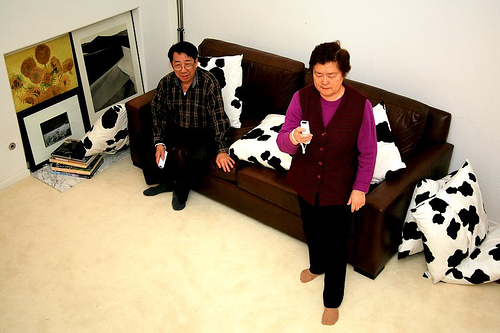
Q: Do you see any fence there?
A: No, there are no fences.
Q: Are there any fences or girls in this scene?
A: No, there are no fences or girls.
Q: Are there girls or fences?
A: No, there are no fences or girls.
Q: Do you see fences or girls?
A: No, there are no fences or girls.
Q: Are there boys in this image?
A: No, there are no boys.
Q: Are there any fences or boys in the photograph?
A: No, there are no boys or fences.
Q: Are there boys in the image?
A: No, there are no boys.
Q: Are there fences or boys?
A: No, there are no boys or fences.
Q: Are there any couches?
A: Yes, there is a couch.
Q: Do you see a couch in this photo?
A: Yes, there is a couch.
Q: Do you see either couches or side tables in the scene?
A: Yes, there is a couch.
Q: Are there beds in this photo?
A: No, there are no beds.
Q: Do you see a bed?
A: No, there are no beds.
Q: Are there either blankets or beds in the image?
A: No, there are no beds or blankets.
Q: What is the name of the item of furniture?
A: The piece of furniture is a couch.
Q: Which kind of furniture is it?
A: The piece of furniture is a couch.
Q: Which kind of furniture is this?
A: This is a couch.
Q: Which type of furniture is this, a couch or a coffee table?
A: This is a couch.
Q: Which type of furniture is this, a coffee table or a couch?
A: This is a couch.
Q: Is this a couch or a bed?
A: This is a couch.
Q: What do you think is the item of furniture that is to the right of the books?
A: The piece of furniture is a couch.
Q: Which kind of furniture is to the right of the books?
A: The piece of furniture is a couch.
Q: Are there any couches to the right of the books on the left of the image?
A: Yes, there is a couch to the right of the books.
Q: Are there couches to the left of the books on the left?
A: No, the couch is to the right of the books.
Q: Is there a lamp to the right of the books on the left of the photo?
A: No, there is a couch to the right of the books.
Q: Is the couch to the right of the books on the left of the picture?
A: Yes, the couch is to the right of the books.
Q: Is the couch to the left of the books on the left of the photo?
A: No, the couch is to the right of the books.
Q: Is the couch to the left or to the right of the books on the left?
A: The couch is to the right of the books.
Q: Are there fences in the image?
A: No, there are no fences.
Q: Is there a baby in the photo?
A: No, there are no babies.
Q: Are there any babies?
A: No, there are no babies.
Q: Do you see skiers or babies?
A: No, there are no babies or skiers.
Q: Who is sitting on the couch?
A: The man is sitting on the couch.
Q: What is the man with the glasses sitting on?
A: The man is sitting on the couch.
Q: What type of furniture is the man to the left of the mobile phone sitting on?
A: The man is sitting on the couch.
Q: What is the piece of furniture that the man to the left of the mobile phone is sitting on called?
A: The piece of furniture is a couch.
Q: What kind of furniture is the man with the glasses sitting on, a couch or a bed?
A: The man is sitting on a couch.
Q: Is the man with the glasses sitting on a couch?
A: Yes, the man is sitting on a couch.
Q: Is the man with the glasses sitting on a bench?
A: No, the man is sitting on a couch.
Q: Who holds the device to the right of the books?
A: The man holds the controller.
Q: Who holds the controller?
A: The man holds the controller.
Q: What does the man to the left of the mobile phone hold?
A: The man holds the controller.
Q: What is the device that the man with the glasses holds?
A: The device is a controller.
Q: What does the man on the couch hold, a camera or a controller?
A: The man holds a controller.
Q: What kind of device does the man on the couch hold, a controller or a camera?
A: The man holds a controller.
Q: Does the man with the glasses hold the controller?
A: Yes, the man holds the controller.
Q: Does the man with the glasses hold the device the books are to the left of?
A: Yes, the man holds the controller.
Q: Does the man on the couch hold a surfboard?
A: No, the man holds the controller.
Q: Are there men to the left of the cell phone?
A: Yes, there is a man to the left of the cell phone.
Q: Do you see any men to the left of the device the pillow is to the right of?
A: Yes, there is a man to the left of the cell phone.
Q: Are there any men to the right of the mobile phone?
A: No, the man is to the left of the mobile phone.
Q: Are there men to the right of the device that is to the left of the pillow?
A: No, the man is to the left of the mobile phone.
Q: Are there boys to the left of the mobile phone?
A: No, there is a man to the left of the mobile phone.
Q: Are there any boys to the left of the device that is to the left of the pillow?
A: No, there is a man to the left of the mobile phone.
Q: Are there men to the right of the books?
A: Yes, there is a man to the right of the books.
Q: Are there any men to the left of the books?
A: No, the man is to the right of the books.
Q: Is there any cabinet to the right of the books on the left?
A: No, there is a man to the right of the books.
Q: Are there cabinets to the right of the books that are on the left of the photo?
A: No, there is a man to the right of the books.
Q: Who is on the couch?
A: The man is on the couch.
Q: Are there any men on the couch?
A: Yes, there is a man on the couch.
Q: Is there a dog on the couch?
A: No, there is a man on the couch.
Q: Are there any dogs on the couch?
A: No, there is a man on the couch.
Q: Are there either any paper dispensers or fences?
A: No, there are no fences or paper dispensers.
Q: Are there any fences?
A: No, there are no fences.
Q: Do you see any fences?
A: No, there are no fences.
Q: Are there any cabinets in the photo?
A: No, there are no cabinets.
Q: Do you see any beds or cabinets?
A: No, there are no cabinets or beds.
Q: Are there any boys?
A: No, there are no boys.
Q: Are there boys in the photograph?
A: No, there are no boys.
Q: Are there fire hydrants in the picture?
A: No, there are no fire hydrants.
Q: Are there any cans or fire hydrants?
A: No, there are no fire hydrants or cans.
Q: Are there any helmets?
A: No, there are no helmets.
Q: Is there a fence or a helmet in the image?
A: No, there are no helmets or fences.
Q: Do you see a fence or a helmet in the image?
A: No, there are no helmets or fences.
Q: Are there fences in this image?
A: No, there are no fences.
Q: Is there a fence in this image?
A: No, there are no fences.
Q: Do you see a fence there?
A: No, there are no fences.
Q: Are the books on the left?
A: Yes, the books are on the left of the image.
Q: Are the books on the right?
A: No, the books are on the left of the image.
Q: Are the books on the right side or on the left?
A: The books are on the left of the image.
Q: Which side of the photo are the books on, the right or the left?
A: The books are on the left of the image.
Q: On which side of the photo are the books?
A: The books are on the left of the image.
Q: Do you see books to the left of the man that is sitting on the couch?
A: Yes, there are books to the left of the man.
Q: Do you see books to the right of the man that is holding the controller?
A: No, the books are to the left of the man.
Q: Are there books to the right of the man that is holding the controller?
A: No, the books are to the left of the man.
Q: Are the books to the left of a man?
A: Yes, the books are to the left of a man.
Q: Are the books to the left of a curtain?
A: No, the books are to the left of a man.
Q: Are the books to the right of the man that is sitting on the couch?
A: No, the books are to the left of the man.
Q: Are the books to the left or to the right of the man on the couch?
A: The books are to the left of the man.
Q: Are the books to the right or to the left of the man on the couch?
A: The books are to the left of the man.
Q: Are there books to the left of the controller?
A: Yes, there are books to the left of the controller.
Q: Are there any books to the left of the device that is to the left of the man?
A: Yes, there are books to the left of the controller.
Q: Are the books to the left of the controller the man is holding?
A: Yes, the books are to the left of the controller.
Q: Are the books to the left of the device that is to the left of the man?
A: Yes, the books are to the left of the controller.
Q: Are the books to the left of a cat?
A: No, the books are to the left of the controller.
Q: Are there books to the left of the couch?
A: Yes, there are books to the left of the couch.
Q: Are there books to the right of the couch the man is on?
A: No, the books are to the left of the couch.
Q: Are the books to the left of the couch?
A: Yes, the books are to the left of the couch.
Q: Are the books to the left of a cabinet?
A: No, the books are to the left of the couch.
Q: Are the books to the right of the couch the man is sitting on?
A: No, the books are to the left of the couch.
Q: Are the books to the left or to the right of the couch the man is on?
A: The books are to the left of the couch.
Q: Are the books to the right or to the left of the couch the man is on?
A: The books are to the left of the couch.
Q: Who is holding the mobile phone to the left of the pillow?
A: The man is holding the mobile phone.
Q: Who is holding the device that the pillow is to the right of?
A: The man is holding the mobile phone.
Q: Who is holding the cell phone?
A: The man is holding the mobile phone.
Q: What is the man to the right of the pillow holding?
A: The man is holding the mobile phone.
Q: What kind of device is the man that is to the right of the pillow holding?
A: The man is holding the cellphone.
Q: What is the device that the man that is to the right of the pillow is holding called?
A: The device is a cell phone.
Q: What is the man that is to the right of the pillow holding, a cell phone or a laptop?
A: The man is holding a cell phone.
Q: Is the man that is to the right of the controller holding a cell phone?
A: Yes, the man is holding a cell phone.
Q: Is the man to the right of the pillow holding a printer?
A: No, the man is holding a cell phone.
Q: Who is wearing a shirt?
A: The man is wearing a shirt.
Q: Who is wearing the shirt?
A: The man is wearing a shirt.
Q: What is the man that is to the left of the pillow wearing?
A: The man is wearing a shirt.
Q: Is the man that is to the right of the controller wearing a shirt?
A: Yes, the man is wearing a shirt.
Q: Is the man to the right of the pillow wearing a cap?
A: No, the man is wearing a shirt.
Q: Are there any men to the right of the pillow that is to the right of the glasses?
A: Yes, there is a man to the right of the pillow.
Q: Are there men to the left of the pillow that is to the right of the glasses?
A: No, the man is to the right of the pillow.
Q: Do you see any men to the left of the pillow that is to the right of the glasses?
A: No, the man is to the right of the pillow.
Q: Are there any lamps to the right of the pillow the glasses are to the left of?
A: No, there is a man to the right of the pillow.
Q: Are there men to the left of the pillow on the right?
A: Yes, there is a man to the left of the pillow.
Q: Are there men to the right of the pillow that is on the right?
A: No, the man is to the left of the pillow.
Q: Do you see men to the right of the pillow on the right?
A: No, the man is to the left of the pillow.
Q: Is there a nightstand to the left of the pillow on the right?
A: No, there is a man to the left of the pillow.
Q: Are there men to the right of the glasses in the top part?
A: Yes, there is a man to the right of the glasses.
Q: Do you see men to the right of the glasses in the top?
A: Yes, there is a man to the right of the glasses.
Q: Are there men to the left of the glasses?
A: No, the man is to the right of the glasses.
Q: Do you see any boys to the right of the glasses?
A: No, there is a man to the right of the glasses.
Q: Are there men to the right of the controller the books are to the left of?
A: Yes, there is a man to the right of the controller.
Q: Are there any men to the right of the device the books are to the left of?
A: Yes, there is a man to the right of the controller.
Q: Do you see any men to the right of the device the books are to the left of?
A: Yes, there is a man to the right of the controller.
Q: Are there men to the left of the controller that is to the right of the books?
A: No, the man is to the right of the controller.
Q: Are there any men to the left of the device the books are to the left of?
A: No, the man is to the right of the controller.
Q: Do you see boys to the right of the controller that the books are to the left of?
A: No, there is a man to the right of the controller.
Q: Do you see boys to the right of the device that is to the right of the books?
A: No, there is a man to the right of the controller.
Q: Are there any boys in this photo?
A: No, there are no boys.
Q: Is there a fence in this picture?
A: No, there are no fences.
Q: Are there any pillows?
A: Yes, there is a pillow.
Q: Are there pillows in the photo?
A: Yes, there is a pillow.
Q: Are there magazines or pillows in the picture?
A: Yes, there is a pillow.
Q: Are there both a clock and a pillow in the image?
A: No, there is a pillow but no clocks.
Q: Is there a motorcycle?
A: No, there are no motorcycles.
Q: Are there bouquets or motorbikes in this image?
A: No, there are no motorbikes or bouquets.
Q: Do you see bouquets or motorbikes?
A: No, there are no motorbikes or bouquets.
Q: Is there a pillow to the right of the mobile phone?
A: Yes, there is a pillow to the right of the mobile phone.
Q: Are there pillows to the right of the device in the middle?
A: Yes, there is a pillow to the right of the mobile phone.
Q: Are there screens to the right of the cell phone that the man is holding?
A: No, there is a pillow to the right of the cellphone.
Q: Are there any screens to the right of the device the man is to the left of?
A: No, there is a pillow to the right of the cellphone.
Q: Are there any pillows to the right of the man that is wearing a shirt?
A: Yes, there is a pillow to the right of the man.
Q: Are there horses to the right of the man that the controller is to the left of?
A: No, there is a pillow to the right of the man.